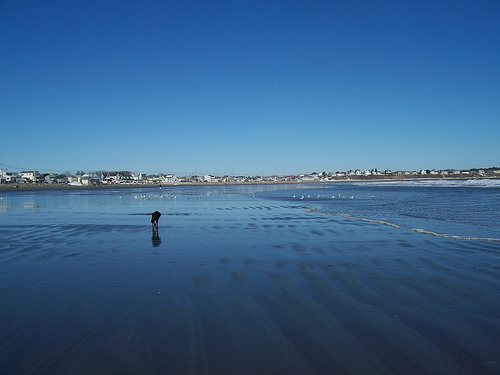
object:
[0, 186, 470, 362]
lake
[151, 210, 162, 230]
man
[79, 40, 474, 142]
sky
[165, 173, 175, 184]
buildings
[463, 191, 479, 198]
water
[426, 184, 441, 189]
wave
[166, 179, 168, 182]
snow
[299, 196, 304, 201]
birds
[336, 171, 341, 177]
houses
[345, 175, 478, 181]
land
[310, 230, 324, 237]
shadow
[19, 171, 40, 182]
house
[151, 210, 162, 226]
animal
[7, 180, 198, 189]
shoreline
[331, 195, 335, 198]
seagulls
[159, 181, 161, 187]
person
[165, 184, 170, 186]
sand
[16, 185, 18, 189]
dog